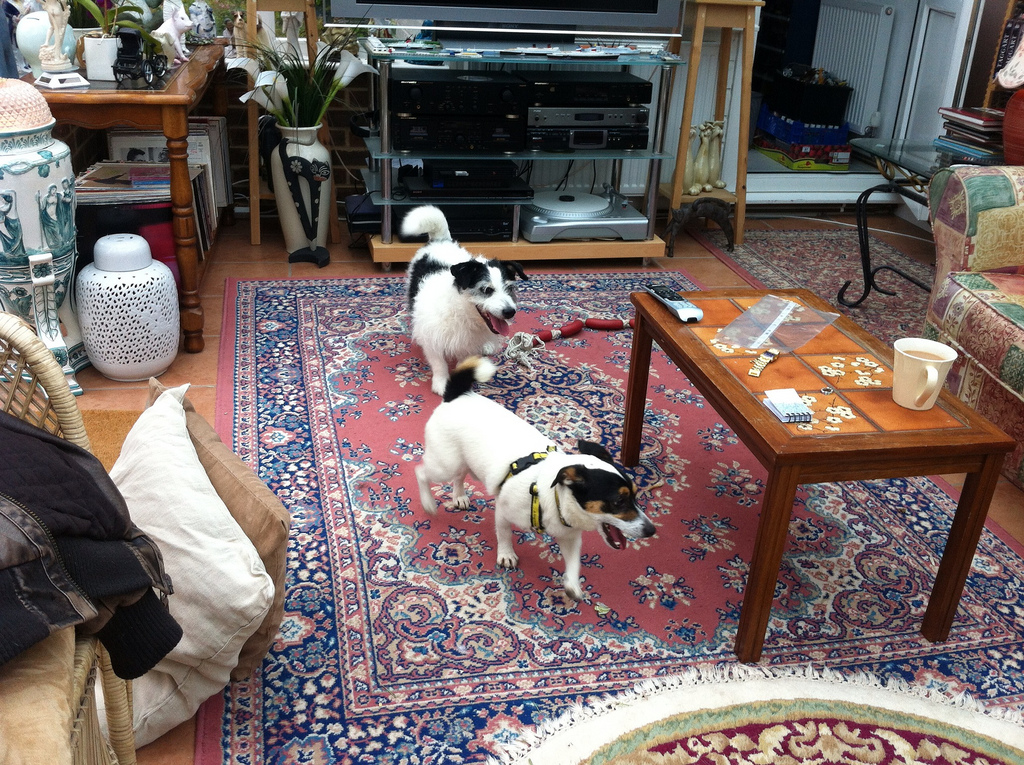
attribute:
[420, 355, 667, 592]
dog — black and white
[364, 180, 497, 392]
dog — black and white, brown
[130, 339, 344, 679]
pillow — brown, beige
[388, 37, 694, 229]
stand — entertainment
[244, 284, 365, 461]
rug — large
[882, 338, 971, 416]
mug — coffee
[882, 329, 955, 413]
mug — white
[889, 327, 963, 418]
coffee mug — white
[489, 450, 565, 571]
harness — yellow, black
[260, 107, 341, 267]
vase — tall, white